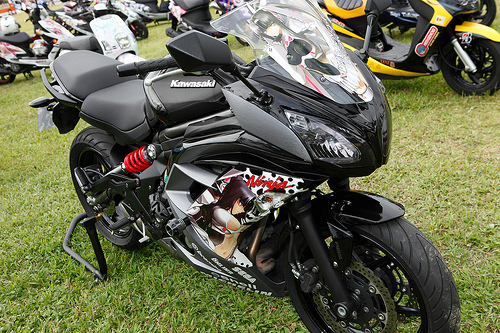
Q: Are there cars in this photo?
A: No, there are no cars.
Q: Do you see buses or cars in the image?
A: No, there are no cars or buses.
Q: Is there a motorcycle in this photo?
A: Yes, there is a motorcycle.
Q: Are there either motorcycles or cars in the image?
A: Yes, there is a motorcycle.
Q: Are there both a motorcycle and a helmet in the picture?
A: No, there is a motorcycle but no helmets.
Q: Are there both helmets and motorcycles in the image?
A: No, there is a motorcycle but no helmets.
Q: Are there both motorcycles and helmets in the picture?
A: No, there is a motorcycle but no helmets.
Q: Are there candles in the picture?
A: No, there are no candles.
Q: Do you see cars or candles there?
A: No, there are no candles or cars.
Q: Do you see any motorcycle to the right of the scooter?
A: Yes, there is a motorcycle to the right of the scooter.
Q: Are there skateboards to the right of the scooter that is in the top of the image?
A: No, there is a motorcycle to the right of the scooter.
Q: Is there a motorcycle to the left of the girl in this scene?
A: Yes, there is a motorcycle to the left of the girl.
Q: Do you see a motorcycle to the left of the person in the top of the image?
A: Yes, there is a motorcycle to the left of the girl.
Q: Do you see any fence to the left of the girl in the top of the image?
A: No, there is a motorcycle to the left of the girl.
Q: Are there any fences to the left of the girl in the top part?
A: No, there is a motorcycle to the left of the girl.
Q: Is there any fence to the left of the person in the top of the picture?
A: No, there is a motorcycle to the left of the girl.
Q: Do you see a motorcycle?
A: Yes, there is a motorcycle.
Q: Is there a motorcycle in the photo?
A: Yes, there is a motorcycle.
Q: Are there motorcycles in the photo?
A: Yes, there is a motorcycle.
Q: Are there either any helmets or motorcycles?
A: Yes, there is a motorcycle.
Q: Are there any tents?
A: No, there are no tents.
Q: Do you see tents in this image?
A: No, there are no tents.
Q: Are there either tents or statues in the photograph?
A: No, there are no tents or statues.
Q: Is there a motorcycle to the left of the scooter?
A: Yes, there is a motorcycle to the left of the scooter.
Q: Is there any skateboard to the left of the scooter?
A: No, there is a motorcycle to the left of the scooter.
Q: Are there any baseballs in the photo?
A: No, there are no baseballs.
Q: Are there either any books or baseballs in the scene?
A: No, there are no baseballs or books.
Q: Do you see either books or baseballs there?
A: No, there are no baseballs or books.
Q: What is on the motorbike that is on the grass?
A: The seat is on the motorcycle.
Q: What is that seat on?
A: The seat is on the motorbike.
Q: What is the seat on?
A: The seat is on the motorbike.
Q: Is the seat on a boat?
A: No, the seat is on the motorbike.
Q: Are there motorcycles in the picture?
A: Yes, there is a motorcycle.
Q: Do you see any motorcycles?
A: Yes, there is a motorcycle.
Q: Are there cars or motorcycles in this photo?
A: Yes, there is a motorcycle.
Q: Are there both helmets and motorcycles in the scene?
A: No, there is a motorcycle but no helmets.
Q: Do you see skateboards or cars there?
A: No, there are no cars or skateboards.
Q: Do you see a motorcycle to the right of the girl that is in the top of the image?
A: Yes, there is a motorcycle to the right of the girl.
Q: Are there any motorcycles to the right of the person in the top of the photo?
A: Yes, there is a motorcycle to the right of the girl.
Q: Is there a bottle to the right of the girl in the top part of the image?
A: No, there is a motorcycle to the right of the girl.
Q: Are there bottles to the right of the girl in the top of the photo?
A: No, there is a motorcycle to the right of the girl.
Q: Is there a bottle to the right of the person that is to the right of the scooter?
A: No, there is a motorcycle to the right of the girl.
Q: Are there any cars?
A: No, there are no cars.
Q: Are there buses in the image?
A: No, there are no buses.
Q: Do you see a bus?
A: No, there are no buses.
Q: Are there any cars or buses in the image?
A: No, there are no buses or cars.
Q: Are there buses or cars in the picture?
A: No, there are no buses or cars.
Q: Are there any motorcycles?
A: Yes, there is a motorcycle.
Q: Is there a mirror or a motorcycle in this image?
A: Yes, there is a motorcycle.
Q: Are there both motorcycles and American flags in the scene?
A: No, there is a motorcycle but no American flags.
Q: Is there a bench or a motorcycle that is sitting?
A: Yes, the motorcycle is sitting.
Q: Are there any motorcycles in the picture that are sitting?
A: Yes, there is a motorcycle that is sitting.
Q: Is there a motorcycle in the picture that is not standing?
A: Yes, there is a motorcycle that is sitting.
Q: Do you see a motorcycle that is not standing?
A: Yes, there is a motorcycle that is sitting .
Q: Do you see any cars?
A: No, there are no cars.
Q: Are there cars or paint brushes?
A: No, there are no cars or paint brushes.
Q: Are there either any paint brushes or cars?
A: No, there are no cars or paint brushes.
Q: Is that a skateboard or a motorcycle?
A: That is a motorcycle.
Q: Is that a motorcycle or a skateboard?
A: That is a motorcycle.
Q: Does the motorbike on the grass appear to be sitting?
A: Yes, the motorbike is sitting.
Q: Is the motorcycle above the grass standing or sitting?
A: The motorbike is sitting.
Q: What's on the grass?
A: The motorbike is on the grass.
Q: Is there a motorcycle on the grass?
A: Yes, there is a motorcycle on the grass.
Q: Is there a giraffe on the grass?
A: No, there is a motorcycle on the grass.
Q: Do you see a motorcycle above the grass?
A: Yes, there is a motorcycle above the grass.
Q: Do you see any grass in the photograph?
A: Yes, there is grass.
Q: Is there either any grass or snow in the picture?
A: Yes, there is grass.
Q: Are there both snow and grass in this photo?
A: No, there is grass but no snow.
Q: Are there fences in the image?
A: No, there are no fences.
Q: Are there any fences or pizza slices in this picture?
A: No, there are no fences or pizza slices.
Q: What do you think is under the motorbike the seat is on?
A: The grass is under the motorbike.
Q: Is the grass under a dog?
A: No, the grass is under the motorcycle.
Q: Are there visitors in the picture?
A: No, there are no visitors.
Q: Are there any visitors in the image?
A: No, there are no visitors.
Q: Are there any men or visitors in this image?
A: No, there are no visitors or men.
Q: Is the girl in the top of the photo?
A: Yes, the girl is in the top of the image.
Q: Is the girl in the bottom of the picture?
A: No, the girl is in the top of the image.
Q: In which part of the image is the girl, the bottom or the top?
A: The girl is in the top of the image.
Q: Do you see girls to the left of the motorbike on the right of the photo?
A: Yes, there is a girl to the left of the motorcycle.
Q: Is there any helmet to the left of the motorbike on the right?
A: No, there is a girl to the left of the motorbike.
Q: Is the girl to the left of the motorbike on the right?
A: Yes, the girl is to the left of the motorcycle.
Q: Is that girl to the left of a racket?
A: No, the girl is to the left of the motorcycle.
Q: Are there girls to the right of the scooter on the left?
A: Yes, there is a girl to the right of the scooter.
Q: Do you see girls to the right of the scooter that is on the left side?
A: Yes, there is a girl to the right of the scooter.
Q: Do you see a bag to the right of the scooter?
A: No, there is a girl to the right of the scooter.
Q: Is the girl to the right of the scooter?
A: Yes, the girl is to the right of the scooter.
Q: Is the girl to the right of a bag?
A: No, the girl is to the right of the scooter.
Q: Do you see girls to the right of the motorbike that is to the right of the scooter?
A: Yes, there is a girl to the right of the motorcycle.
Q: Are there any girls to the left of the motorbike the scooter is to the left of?
A: No, the girl is to the right of the motorbike.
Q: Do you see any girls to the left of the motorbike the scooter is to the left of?
A: No, the girl is to the right of the motorbike.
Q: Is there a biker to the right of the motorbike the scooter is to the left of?
A: No, there is a girl to the right of the motorcycle.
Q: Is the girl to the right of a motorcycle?
A: Yes, the girl is to the right of a motorcycle.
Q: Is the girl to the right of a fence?
A: No, the girl is to the right of a motorcycle.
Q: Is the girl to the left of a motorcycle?
A: No, the girl is to the right of a motorcycle.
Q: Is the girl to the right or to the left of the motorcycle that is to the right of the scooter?
A: The girl is to the right of the motorbike.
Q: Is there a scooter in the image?
A: Yes, there is a scooter.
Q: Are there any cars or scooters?
A: Yes, there is a scooter.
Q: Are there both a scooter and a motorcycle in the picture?
A: Yes, there are both a scooter and a motorcycle.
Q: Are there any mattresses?
A: No, there are no mattresses.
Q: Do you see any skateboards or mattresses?
A: No, there are no mattresses or skateboards.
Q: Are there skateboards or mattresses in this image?
A: No, there are no mattresses or skateboards.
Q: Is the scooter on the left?
A: Yes, the scooter is on the left of the image.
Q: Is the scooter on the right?
A: No, the scooter is on the left of the image.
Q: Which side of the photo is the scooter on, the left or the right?
A: The scooter is on the left of the image.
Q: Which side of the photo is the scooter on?
A: The scooter is on the left of the image.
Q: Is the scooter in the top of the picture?
A: Yes, the scooter is in the top of the image.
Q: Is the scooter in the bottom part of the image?
A: No, the scooter is in the top of the image.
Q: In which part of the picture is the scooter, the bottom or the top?
A: The scooter is in the top of the image.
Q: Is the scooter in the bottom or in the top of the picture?
A: The scooter is in the top of the image.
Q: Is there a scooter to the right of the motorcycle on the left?
A: Yes, there is a scooter to the right of the motorcycle.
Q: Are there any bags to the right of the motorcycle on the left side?
A: No, there is a scooter to the right of the motorbike.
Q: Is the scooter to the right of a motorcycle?
A: Yes, the scooter is to the right of a motorcycle.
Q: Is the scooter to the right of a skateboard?
A: No, the scooter is to the right of a motorcycle.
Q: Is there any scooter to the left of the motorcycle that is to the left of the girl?
A: Yes, there is a scooter to the left of the motorbike.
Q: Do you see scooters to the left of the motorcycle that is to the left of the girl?
A: Yes, there is a scooter to the left of the motorbike.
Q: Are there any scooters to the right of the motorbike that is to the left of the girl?
A: No, the scooter is to the left of the motorcycle.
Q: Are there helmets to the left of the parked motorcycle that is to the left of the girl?
A: No, there is a scooter to the left of the motorbike.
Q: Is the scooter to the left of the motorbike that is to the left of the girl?
A: Yes, the scooter is to the left of the motorbike.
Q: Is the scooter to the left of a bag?
A: No, the scooter is to the left of the motorbike.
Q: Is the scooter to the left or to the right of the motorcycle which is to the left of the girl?
A: The scooter is to the left of the motorbike.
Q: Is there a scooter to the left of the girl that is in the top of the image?
A: Yes, there is a scooter to the left of the girl.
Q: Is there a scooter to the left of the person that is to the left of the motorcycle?
A: Yes, there is a scooter to the left of the girl.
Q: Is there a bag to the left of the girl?
A: No, there is a scooter to the left of the girl.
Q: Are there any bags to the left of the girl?
A: No, there is a scooter to the left of the girl.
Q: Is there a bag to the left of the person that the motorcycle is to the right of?
A: No, there is a scooter to the left of the girl.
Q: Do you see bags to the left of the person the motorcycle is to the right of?
A: No, there is a scooter to the left of the girl.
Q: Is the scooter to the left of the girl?
A: Yes, the scooter is to the left of the girl.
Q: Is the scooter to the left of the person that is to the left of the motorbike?
A: Yes, the scooter is to the left of the girl.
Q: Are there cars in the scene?
A: No, there are no cars.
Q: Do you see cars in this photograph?
A: No, there are no cars.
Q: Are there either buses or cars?
A: No, there are no cars or buses.